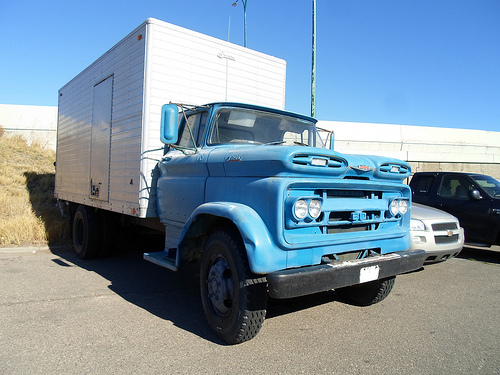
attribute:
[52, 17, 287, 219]
trailer — white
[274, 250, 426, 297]
bumper — black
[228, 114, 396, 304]
truck — blue 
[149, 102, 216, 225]
door — blue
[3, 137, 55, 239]
grass — dead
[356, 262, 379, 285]
licenseplate — white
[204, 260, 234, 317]
hub cap — blue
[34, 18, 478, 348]
truck — blue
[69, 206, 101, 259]
tire — black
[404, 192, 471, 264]
car — silver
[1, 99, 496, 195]
wall — white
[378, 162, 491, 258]
car — black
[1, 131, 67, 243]
grass — dead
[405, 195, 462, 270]
car — parked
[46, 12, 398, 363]
truck — blue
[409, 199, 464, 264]
silver car — parked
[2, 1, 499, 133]
sky — blue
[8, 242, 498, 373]
road — gray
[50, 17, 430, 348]
blue truck — parked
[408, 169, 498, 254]
truck — black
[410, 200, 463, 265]
car — gray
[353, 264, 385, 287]
license plate — white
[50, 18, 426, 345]
truck — parked, blue, blue and white, light blue, big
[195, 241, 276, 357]
tire — black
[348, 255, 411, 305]
tire — black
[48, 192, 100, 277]
tire — black